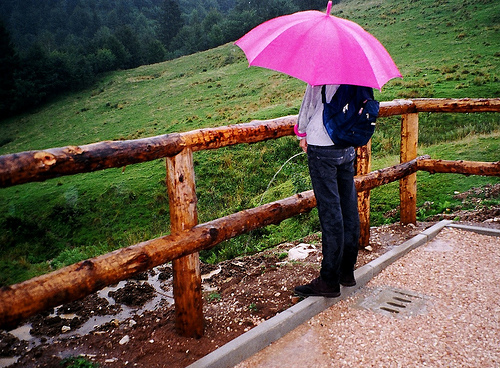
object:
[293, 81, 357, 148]
shirt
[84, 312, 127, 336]
ice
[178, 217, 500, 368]
cement curb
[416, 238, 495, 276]
ground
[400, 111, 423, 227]
post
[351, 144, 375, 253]
post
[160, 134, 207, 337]
post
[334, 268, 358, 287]
shoes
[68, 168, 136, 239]
grass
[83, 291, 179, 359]
dirt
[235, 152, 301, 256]
stream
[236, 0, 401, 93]
umbrella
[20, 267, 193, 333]
snow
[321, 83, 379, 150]
backpack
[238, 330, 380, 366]
gravel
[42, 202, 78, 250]
weeds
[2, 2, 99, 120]
tree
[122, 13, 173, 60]
tree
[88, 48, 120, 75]
tree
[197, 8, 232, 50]
tree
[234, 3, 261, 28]
tree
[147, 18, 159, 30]
leaf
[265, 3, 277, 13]
leaf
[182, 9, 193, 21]
leaf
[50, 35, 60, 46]
leaf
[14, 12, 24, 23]
leaf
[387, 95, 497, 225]
log fence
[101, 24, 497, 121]
grass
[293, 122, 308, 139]
handle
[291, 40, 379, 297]
man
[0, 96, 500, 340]
fence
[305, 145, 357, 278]
denim jeans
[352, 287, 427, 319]
drain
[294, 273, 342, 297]
boots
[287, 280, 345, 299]
foot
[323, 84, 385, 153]
back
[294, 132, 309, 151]
hand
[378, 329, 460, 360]
ground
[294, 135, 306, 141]
tip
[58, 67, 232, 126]
field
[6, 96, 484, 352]
overlook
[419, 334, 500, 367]
gravel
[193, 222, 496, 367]
curb